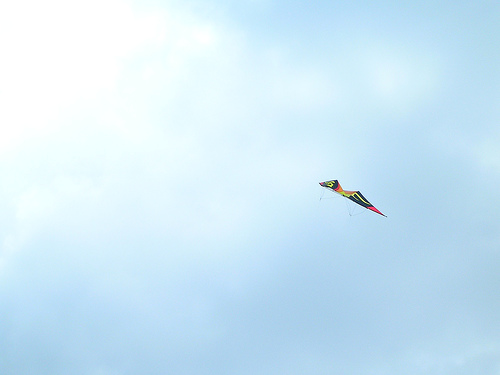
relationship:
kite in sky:
[314, 162, 391, 224] [8, 63, 498, 356]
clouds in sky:
[2, 2, 157, 129] [8, 63, 498, 356]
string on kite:
[312, 197, 335, 211] [312, 163, 385, 239]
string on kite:
[312, 197, 335, 211] [316, 167, 385, 224]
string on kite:
[305, 183, 336, 207] [308, 169, 380, 230]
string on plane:
[312, 197, 335, 211] [314, 175, 395, 221]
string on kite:
[305, 183, 336, 207] [305, 167, 388, 241]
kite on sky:
[314, 162, 391, 224] [8, 63, 498, 356]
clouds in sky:
[2, 2, 157, 129] [19, 84, 499, 373]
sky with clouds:
[5, 2, 497, 372] [27, 120, 299, 290]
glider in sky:
[308, 174, 391, 223] [8, 63, 498, 356]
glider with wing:
[308, 174, 391, 223] [349, 179, 394, 221]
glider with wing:
[308, 174, 391, 223] [340, 186, 386, 221]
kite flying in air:
[303, 165, 387, 224] [9, 33, 367, 299]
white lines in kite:
[347, 197, 371, 208] [321, 174, 392, 247]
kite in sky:
[303, 165, 387, 224] [5, 2, 497, 372]